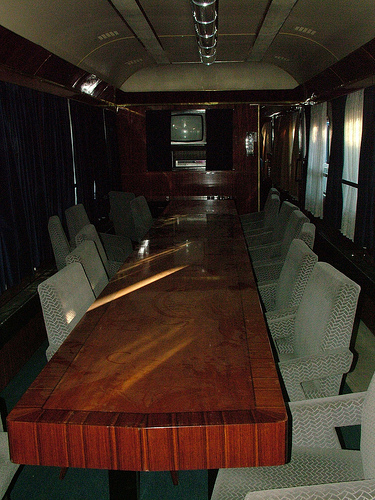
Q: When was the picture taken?
A: Daytime.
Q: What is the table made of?
A: Wood.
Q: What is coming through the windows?
A: Sunlight.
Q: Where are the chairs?
A: Around the table.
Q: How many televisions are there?
A: One.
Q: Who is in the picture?
A: Nobody.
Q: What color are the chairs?
A: Gray.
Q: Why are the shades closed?
A: To block the sunlight.